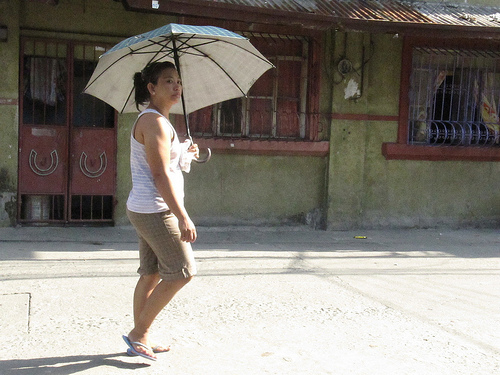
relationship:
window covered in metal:
[178, 19, 329, 158] [188, 33, 307, 136]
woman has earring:
[120, 60, 203, 365] [151, 90, 158, 98]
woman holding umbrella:
[120, 60, 203, 365] [79, 22, 279, 166]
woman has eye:
[120, 60, 203, 365] [166, 78, 172, 85]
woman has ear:
[120, 60, 203, 365] [146, 81, 157, 97]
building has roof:
[2, 1, 499, 229] [138, 0, 499, 38]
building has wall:
[2, 1, 499, 229] [1, 0, 498, 226]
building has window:
[2, 1, 499, 229] [178, 19, 329, 158]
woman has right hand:
[120, 60, 203, 365] [177, 218, 199, 244]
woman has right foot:
[120, 60, 203, 365] [126, 331, 157, 359]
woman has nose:
[120, 60, 203, 365] [174, 83, 181, 93]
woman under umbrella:
[120, 60, 203, 365] [79, 22, 279, 166]